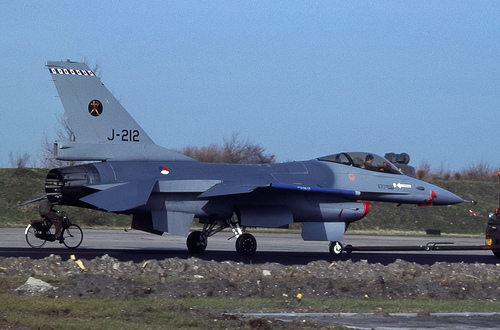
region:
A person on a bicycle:
[27, 192, 84, 247]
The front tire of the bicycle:
[61, 222, 82, 244]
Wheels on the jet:
[183, 232, 255, 254]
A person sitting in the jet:
[362, 153, 374, 167]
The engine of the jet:
[46, 164, 98, 200]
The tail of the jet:
[46, 59, 160, 160]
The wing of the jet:
[205, 176, 407, 195]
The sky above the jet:
[0, 0, 497, 167]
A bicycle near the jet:
[26, 213, 83, 246]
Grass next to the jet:
[3, 299, 495, 328]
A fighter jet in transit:
[45, 54, 498, 263]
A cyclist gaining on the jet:
[24, 195, 84, 250]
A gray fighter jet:
[30, 54, 474, 260]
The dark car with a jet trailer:
[27, 61, 498, 266]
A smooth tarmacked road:
[0, 227, 498, 267]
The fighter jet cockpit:
[319, 147, 400, 177]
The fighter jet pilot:
[363, 152, 386, 173]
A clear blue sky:
[1, 0, 498, 179]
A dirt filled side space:
[0, 253, 498, 325]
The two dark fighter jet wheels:
[185, 231, 257, 258]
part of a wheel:
[321, 220, 348, 289]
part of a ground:
[279, 253, 311, 298]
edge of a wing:
[316, 184, 341, 206]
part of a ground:
[259, 290, 281, 309]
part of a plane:
[325, 143, 362, 192]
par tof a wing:
[246, 236, 272, 282]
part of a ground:
[238, 255, 275, 301]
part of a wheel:
[333, 234, 371, 259]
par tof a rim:
[233, 221, 270, 293]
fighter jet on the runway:
[38, 46, 499, 260]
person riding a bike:
[18, 188, 91, 259]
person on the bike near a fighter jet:
[31, 180, 88, 260]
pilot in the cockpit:
[338, 145, 386, 172]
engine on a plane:
[34, 160, 101, 212]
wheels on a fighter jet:
[186, 224, 267, 260]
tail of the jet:
[43, 57, 115, 102]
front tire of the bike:
[65, 225, 82, 247]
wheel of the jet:
[232, 233, 258, 255]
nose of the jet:
[437, 183, 480, 213]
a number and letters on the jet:
[100, 128, 140, 143]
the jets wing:
[200, 178, 276, 204]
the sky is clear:
[185, 33, 353, 105]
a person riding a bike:
[31, 190, 63, 218]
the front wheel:
[327, 241, 347, 255]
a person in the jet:
[354, 153, 379, 168]